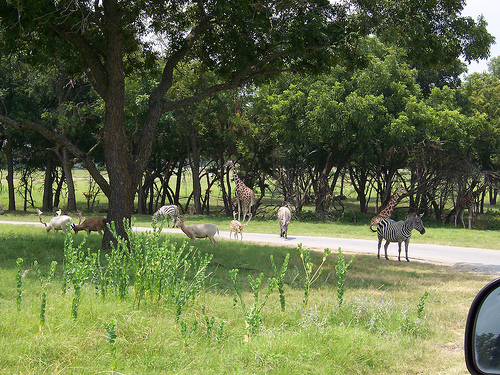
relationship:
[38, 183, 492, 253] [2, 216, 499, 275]
animals on path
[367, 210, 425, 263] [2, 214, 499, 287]
animals walking down path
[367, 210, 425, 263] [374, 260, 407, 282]
animals standing in grass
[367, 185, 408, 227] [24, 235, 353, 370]
animal seated in grass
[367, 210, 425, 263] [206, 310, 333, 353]
animals standing in grass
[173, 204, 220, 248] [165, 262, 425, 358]
animal standing in grass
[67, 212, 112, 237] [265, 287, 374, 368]
animal standing in grass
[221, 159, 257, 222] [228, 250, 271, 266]
animal wandering shade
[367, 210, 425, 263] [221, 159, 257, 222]
animals wandering with animal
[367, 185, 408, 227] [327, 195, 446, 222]
animal in shade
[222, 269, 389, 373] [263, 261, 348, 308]
flowers on plants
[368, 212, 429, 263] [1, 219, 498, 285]
animal on road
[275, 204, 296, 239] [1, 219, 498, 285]
animal on road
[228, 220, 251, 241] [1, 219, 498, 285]
animal on road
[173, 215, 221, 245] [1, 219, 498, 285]
animal on road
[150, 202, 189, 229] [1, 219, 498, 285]
animal on road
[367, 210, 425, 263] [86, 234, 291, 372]
animals in field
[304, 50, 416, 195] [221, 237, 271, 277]
fire hydrant providing shade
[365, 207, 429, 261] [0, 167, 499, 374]
animal on field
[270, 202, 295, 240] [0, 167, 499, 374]
animal on field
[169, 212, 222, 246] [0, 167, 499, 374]
animal on field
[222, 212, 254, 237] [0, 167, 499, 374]
animal on field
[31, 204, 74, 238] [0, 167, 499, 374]
animal on field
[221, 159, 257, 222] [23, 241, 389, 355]
animal in grass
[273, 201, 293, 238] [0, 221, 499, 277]
animal on path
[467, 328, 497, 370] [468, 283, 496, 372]
reflection on mirror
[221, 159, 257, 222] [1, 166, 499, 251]
animal on grass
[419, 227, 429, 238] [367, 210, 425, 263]
snout on animals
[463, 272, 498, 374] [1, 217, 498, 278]
mirror by road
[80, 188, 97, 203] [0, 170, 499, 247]
animal in field